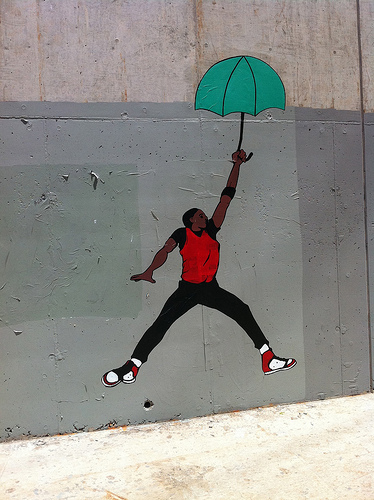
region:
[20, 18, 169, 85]
piece of a concrete wall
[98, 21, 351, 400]
painting of a jumping man holding an umbrella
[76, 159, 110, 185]
nail sticking out of a wall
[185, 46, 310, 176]
painting of an umbrella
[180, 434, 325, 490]
piece of a concrete sidewalk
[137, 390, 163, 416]
hole in a concrete wall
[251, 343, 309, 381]
painting of a sneaker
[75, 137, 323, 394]
jumping man painted on the wall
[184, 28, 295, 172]
green umbrella painting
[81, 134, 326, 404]
painting of a man wearing a red jersey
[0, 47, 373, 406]
Mural paint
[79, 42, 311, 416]
Paint of a man with an umbrella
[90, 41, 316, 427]
Picture is painted over a grey surface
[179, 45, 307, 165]
Umbrella is green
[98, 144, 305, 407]
Picture of boy jumping in the air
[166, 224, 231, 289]
Red tank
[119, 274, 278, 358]
Black pants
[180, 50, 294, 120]
Canopy of umbrella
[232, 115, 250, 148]
Shaft of umbrella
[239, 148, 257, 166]
Handle of umbrella is black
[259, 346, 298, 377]
a red and white shoe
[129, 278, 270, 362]
a pair of black pants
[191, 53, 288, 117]
a green umbrella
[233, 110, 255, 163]
a black umbrella handle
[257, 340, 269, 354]
a white sock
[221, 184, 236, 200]
a black arm band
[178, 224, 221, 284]
a red tank top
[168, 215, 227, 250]
a black tee shirt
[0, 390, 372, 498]
a white cement floor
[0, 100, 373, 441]
gray paint on the wall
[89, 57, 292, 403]
art painted on city wall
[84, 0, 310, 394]
man floating away with umbrella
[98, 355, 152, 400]
black, white and red sneakers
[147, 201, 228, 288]
red tank top with black t-shirt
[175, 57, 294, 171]
green umbrella with black handle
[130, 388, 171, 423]
small hole in grey wall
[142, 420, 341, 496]
light colored city sidewalk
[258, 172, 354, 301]
painted grey building wall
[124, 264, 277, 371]
man in black pants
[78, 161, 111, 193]
small piece of metal emerging from building wall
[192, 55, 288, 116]
Painting of a green umbrella top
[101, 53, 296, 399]
Painting of a black man holding on to an umbrella rising in the air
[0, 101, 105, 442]
A wall painted gray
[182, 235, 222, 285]
A red shirt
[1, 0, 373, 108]
Concrete top of wall unpainted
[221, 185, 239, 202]
A black wristband on the man's arm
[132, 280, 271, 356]
Man wearing black pants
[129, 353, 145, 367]
A white sock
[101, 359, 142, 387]
A black, red and white shoe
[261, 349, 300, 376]
A red, white and black shoe